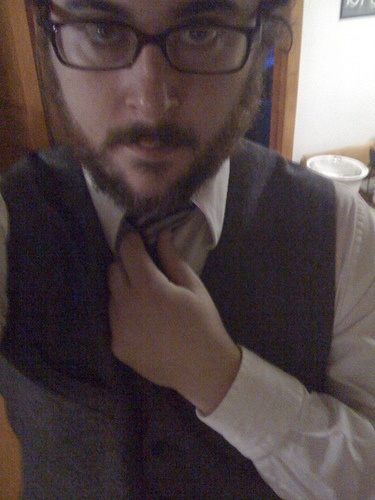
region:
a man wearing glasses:
[27, 4, 288, 232]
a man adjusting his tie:
[93, 192, 270, 395]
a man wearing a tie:
[6, 1, 361, 371]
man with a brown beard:
[21, 2, 314, 220]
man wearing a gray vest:
[3, 2, 352, 492]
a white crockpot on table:
[295, 140, 372, 202]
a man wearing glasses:
[43, 9, 265, 78]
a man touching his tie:
[92, 201, 207, 374]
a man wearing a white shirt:
[239, 340, 359, 499]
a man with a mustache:
[107, 116, 203, 155]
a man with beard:
[52, 93, 247, 226]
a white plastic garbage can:
[312, 150, 366, 184]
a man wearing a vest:
[180, 176, 351, 493]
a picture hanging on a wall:
[337, 0, 374, 19]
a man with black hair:
[247, 7, 293, 99]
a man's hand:
[103, 214, 231, 407]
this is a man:
[24, 24, 285, 371]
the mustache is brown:
[86, 112, 214, 178]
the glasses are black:
[34, 3, 266, 74]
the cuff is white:
[195, 341, 304, 461]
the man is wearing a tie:
[0, 0, 373, 498]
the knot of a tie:
[126, 209, 192, 244]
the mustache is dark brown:
[101, 119, 198, 155]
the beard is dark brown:
[35, 16, 266, 217]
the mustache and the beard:
[36, 24, 264, 217]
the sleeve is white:
[194, 180, 373, 498]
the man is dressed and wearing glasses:
[1, 0, 373, 497]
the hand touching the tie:
[109, 202, 227, 394]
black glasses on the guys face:
[28, 8, 278, 82]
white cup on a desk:
[308, 134, 373, 200]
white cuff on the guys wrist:
[219, 326, 300, 476]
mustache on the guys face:
[102, 104, 207, 173]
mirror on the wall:
[338, 1, 373, 27]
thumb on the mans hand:
[147, 219, 211, 297]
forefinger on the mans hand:
[118, 227, 154, 290]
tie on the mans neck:
[129, 207, 198, 239]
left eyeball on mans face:
[178, 27, 234, 52]